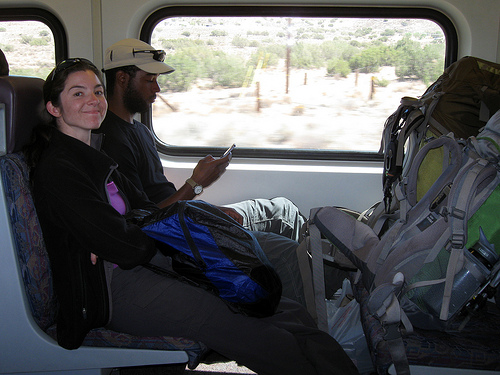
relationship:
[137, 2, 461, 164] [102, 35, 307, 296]
window behind man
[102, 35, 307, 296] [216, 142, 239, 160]
man on phone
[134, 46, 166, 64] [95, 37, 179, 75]
sunglasses on hat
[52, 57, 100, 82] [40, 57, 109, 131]
sunglasses on head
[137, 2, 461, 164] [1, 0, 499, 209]
window on side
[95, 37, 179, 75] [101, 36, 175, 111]
hat on head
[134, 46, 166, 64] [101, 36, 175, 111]
sunglasses on head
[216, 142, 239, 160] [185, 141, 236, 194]
phone in hand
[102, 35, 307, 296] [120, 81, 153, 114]
man has beard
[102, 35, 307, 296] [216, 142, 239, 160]
man looking at phone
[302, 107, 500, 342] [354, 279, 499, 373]
backpack on seat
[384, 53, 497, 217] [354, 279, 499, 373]
backpack on seat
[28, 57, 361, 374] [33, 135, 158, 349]
woman wearing jacket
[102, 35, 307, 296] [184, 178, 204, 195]
man wearing watch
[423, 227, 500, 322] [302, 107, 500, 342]
water bottle on backpack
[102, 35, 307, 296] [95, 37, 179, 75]
man wearing hat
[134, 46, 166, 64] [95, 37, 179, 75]
sunglasses on top of hat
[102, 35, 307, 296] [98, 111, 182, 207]
man wearing shirt